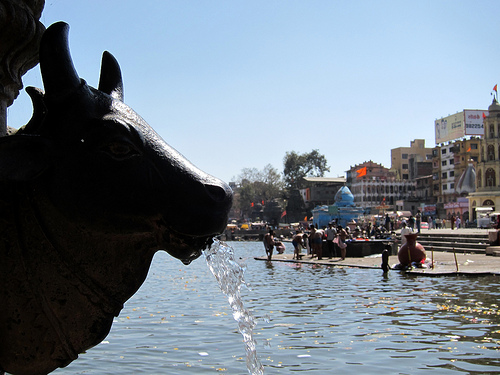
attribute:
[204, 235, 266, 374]
water — fountain, streaming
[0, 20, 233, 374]
statue — black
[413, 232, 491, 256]
steps — concrete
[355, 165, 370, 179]
flag — bright orange, orange, flying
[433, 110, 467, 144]
billboard — yellow, yelow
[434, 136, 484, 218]
building — tall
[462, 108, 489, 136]
billboard — white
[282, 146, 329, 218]
tree — green, tall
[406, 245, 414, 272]
pole — yellow, short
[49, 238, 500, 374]
water — reflective, immense, blue, clear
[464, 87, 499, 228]
building — windowed, tall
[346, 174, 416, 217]
building — short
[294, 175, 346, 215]
building — short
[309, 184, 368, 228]
building — pointed, light blue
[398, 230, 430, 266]
vase — red, huge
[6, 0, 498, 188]
sky — blue